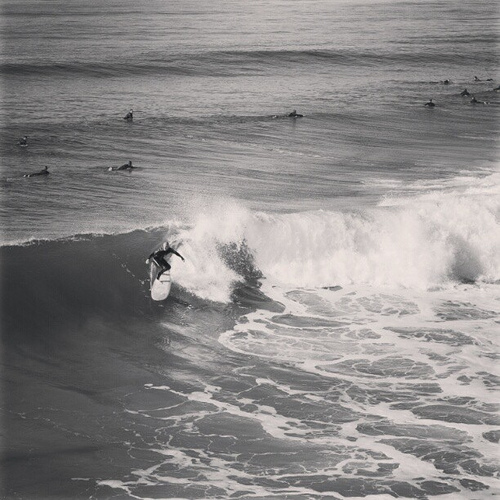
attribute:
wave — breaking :
[181, 222, 243, 303]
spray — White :
[3, 170, 499, 498]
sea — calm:
[4, 2, 499, 59]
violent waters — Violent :
[175, 167, 497, 312]